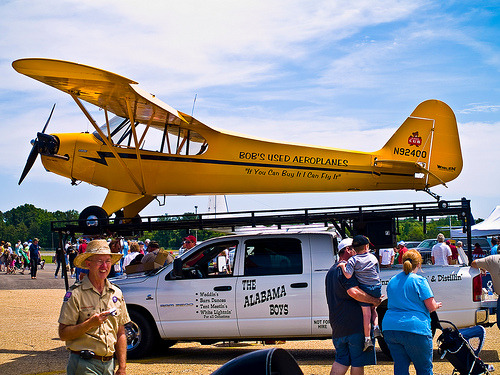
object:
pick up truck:
[106, 226, 489, 361]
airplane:
[8, 58, 464, 234]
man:
[324, 237, 385, 375]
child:
[337, 235, 383, 353]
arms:
[339, 272, 377, 304]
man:
[58, 238, 131, 375]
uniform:
[59, 273, 130, 375]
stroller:
[437, 320, 493, 375]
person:
[28, 238, 41, 279]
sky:
[0, 1, 499, 221]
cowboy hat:
[73, 239, 124, 270]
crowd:
[52, 234, 203, 280]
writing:
[280, 285, 287, 297]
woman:
[381, 249, 442, 374]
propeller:
[17, 102, 61, 186]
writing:
[239, 151, 246, 158]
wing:
[11, 58, 216, 145]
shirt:
[381, 271, 435, 338]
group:
[0, 237, 46, 280]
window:
[165, 240, 239, 281]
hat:
[352, 235, 374, 248]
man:
[180, 235, 204, 269]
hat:
[184, 234, 196, 243]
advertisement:
[239, 151, 349, 181]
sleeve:
[58, 289, 81, 326]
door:
[154, 236, 240, 342]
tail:
[375, 100, 464, 191]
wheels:
[77, 205, 110, 235]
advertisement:
[157, 278, 289, 322]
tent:
[448, 204, 500, 239]